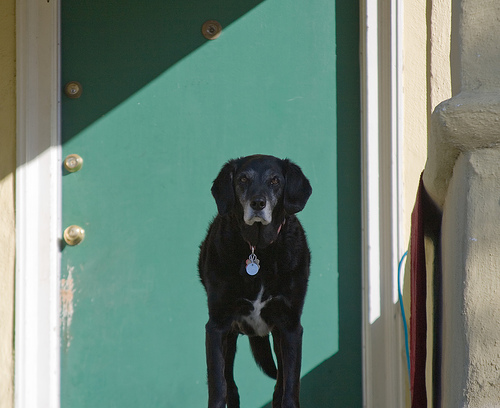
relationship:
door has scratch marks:
[61, 0, 362, 406] [60, 263, 76, 353]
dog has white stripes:
[198, 152, 315, 407] [226, 281, 295, 339]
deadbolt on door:
[67, 82, 81, 95] [61, 0, 362, 406]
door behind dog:
[61, 0, 362, 406] [198, 152, 315, 407]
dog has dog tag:
[198, 152, 315, 407] [246, 247, 260, 278]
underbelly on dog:
[239, 300, 272, 340] [198, 152, 315, 407]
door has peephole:
[61, 0, 362, 406] [202, 20, 225, 42]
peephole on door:
[202, 20, 225, 42] [61, 0, 362, 406]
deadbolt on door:
[59, 152, 86, 174] [61, 0, 362, 406]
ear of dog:
[279, 157, 312, 218] [198, 152, 315, 407]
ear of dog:
[206, 157, 241, 218] [198, 152, 315, 407]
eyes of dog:
[236, 173, 284, 190] [198, 152, 315, 407]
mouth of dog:
[241, 205, 276, 225] [198, 152, 315, 407]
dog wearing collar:
[198, 152, 315, 407] [226, 213, 288, 249]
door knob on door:
[63, 225, 84, 249] [61, 0, 362, 406]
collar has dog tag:
[226, 213, 288, 249] [246, 247, 260, 278]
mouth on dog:
[241, 205, 276, 225] [198, 152, 315, 407]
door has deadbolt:
[61, 0, 362, 406] [67, 82, 81, 95]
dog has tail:
[198, 152, 315, 407] [250, 333, 281, 380]